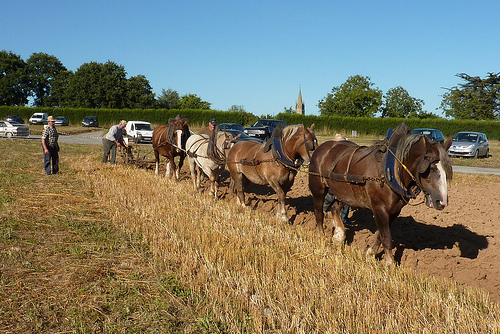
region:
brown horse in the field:
[312, 115, 465, 255]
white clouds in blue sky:
[56, 10, 91, 40]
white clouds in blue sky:
[126, 10, 166, 55]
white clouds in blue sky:
[201, 32, 226, 49]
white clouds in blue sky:
[235, 15, 280, 60]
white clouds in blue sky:
[190, 40, 227, 86]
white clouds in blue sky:
[320, 31, 370, 66]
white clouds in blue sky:
[375, 10, 420, 47]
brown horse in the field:
[225, 95, 303, 207]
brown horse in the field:
[187, 127, 227, 174]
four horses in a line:
[149, 109, 451, 256]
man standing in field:
[36, 106, 63, 171]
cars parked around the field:
[2, 104, 493, 159]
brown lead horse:
[305, 123, 459, 266]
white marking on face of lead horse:
[430, 155, 449, 196]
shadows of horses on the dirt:
[182, 151, 488, 266]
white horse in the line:
[185, 121, 233, 193]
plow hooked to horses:
[120, 124, 152, 170]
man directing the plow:
[95, 117, 131, 157]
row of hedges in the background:
[5, 103, 497, 143]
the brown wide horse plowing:
[150, 117, 187, 172]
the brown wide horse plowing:
[185, 128, 237, 193]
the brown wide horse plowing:
[217, 122, 317, 220]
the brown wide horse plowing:
[300, 122, 452, 267]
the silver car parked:
[449, 128, 485, 158]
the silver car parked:
[2, 119, 29, 139]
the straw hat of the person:
[44, 114, 55, 122]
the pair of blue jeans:
[40, 144, 60, 171]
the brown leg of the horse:
[369, 198, 394, 265]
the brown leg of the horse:
[328, 194, 345, 241]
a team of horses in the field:
[147, 122, 457, 270]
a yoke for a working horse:
[384, 128, 449, 200]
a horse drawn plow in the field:
[120, 132, 157, 169]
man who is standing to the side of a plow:
[100, 115, 129, 164]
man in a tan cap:
[40, 114, 61, 180]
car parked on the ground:
[445, 130, 490, 159]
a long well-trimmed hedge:
[2, 107, 259, 127]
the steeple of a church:
[294, 84, 305, 118]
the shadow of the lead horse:
[392, 212, 494, 267]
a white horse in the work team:
[182, 127, 233, 200]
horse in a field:
[293, 129, 455, 266]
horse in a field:
[223, 117, 333, 224]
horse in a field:
[179, 123, 245, 202]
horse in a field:
[146, 118, 198, 181]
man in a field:
[97, 114, 135, 167]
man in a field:
[31, 110, 63, 182]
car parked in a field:
[442, 127, 492, 163]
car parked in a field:
[405, 123, 446, 143]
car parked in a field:
[25, 107, 51, 129]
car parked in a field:
[50, 112, 72, 129]